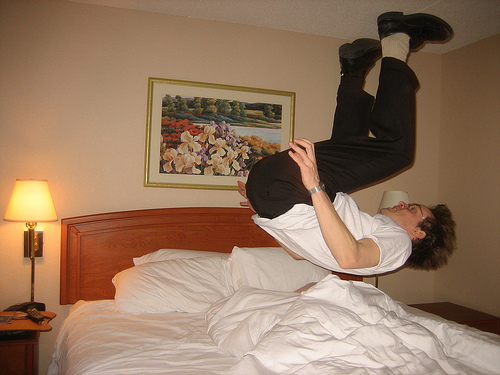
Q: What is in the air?
A: A person.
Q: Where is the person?
A: Above the bed.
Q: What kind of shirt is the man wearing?
A: T shirt.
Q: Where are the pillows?
A: On the bed.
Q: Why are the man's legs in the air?
A: He is doing a flip.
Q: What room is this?
A: Bedroom.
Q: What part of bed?
A: Comforter.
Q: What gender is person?
A: Male.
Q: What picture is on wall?
A: Floral.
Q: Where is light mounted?
A: Wall.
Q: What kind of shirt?
A: Tshirt.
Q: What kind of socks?
A: Tan.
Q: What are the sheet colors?
A: White.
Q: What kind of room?
A: Hotel.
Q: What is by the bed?
A: Illuminayydd.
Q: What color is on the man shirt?
A: White shirt.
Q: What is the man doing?
A: Slipin g on bed.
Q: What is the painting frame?
A: Gold frame.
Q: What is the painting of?
A: Colourful flowers.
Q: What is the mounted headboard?
A: Mountain headboard.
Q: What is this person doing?
A: Jumping on the bed.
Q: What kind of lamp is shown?
A: A wall mounted lamp.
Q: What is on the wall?
A: A picture.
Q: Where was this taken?
A: At a hotel.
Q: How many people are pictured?
A: One.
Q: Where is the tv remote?
A: On the nightstand.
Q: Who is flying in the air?
A: A man.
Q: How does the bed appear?
A: Unmade.